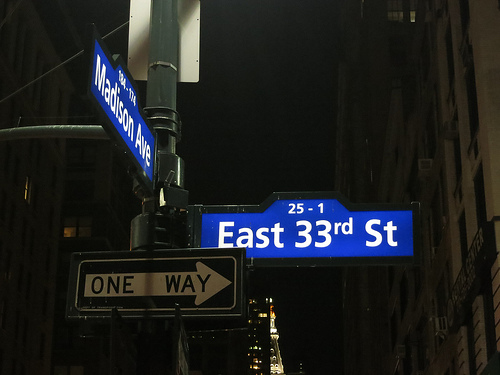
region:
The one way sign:
[69, 248, 251, 325]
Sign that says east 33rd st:
[193, 193, 427, 265]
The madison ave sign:
[89, 45, 161, 188]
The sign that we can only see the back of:
[129, 2, 216, 88]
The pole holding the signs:
[139, 0, 189, 374]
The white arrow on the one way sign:
[83, 263, 231, 305]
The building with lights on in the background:
[241, 291, 286, 373]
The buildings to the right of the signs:
[333, 1, 499, 374]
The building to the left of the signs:
[1, 7, 135, 359]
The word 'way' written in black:
[161, 268, 215, 293]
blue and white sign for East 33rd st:
[198, 189, 423, 272]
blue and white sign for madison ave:
[87, 35, 160, 185]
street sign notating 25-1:
[197, 180, 415, 285]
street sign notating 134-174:
[88, 27, 159, 190]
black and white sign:
[61, 238, 252, 333]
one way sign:
[59, 236, 260, 336]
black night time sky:
[218, 27, 305, 149]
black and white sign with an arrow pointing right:
[56, 236, 263, 332]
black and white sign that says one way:
[61, 235, 241, 325]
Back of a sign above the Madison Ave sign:
[117, 1, 212, 91]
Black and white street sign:
[81, 258, 241, 313]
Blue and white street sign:
[198, 195, 413, 260]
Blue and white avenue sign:
[98, 45, 158, 175]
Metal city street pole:
[148, 2, 180, 162]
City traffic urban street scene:
[251, 294, 283, 374]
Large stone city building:
[357, 12, 499, 374]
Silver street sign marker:
[131, 1, 202, 82]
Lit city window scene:
[60, 220, 90, 237]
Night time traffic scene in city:
[243, 294, 283, 374]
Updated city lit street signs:
[195, 200, 417, 260]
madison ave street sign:
[14, 24, 444, 321]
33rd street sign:
[178, 156, 407, 318]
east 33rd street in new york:
[189, 163, 421, 333]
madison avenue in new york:
[56, 25, 201, 232]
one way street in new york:
[56, 243, 281, 341]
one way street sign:
[66, 247, 266, 340]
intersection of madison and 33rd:
[66, 20, 453, 313]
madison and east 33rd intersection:
[68, 19, 453, 316]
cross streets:
[52, 57, 417, 346]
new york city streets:
[42, 67, 412, 364]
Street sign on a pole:
[81, 24, 178, 186]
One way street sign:
[55, 238, 270, 323]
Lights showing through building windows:
[47, 202, 122, 251]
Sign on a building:
[425, 206, 498, 351]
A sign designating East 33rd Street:
[188, 189, 433, 266]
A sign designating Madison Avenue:
[76, 29, 186, 187]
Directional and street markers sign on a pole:
[49, 6, 436, 334]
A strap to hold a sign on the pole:
[141, 55, 191, 82]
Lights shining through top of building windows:
[369, 3, 434, 35]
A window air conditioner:
[428, 308, 459, 345]